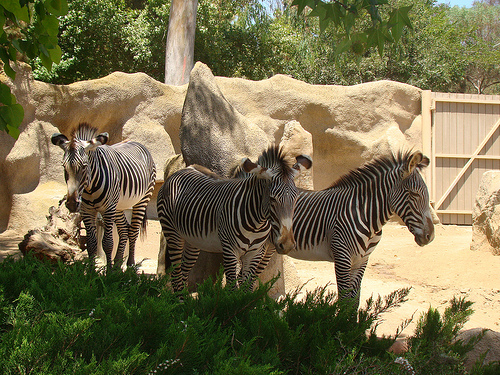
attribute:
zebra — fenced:
[47, 120, 158, 260]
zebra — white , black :
[47, 135, 153, 262]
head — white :
[46, 126, 112, 211]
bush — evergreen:
[7, 273, 457, 374]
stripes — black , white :
[180, 187, 262, 237]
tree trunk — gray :
[153, 1, 208, 91]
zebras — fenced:
[41, 120, 432, 330]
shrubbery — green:
[405, 294, 487, 374]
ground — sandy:
[430, 252, 495, 292]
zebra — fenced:
[51, 122, 156, 274]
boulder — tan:
[0, 57, 440, 260]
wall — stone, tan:
[33, 67, 449, 184]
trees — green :
[224, 12, 480, 90]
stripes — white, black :
[151, 145, 318, 303]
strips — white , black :
[173, 184, 256, 239]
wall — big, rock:
[3, 55, 424, 275]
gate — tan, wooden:
[423, 87, 498, 226]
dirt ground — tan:
[417, 270, 477, 297]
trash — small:
[366, 339, 443, 360]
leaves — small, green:
[277, 4, 448, 63]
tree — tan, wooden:
[165, 0, 198, 85]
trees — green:
[6, 0, 498, 107]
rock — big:
[178, 60, 270, 178]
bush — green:
[5, 252, 497, 372]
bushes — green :
[3, 260, 339, 374]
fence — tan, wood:
[421, 90, 498, 225]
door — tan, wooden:
[428, 87, 497, 226]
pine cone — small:
[151, 361, 198, 373]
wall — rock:
[24, 65, 448, 153]